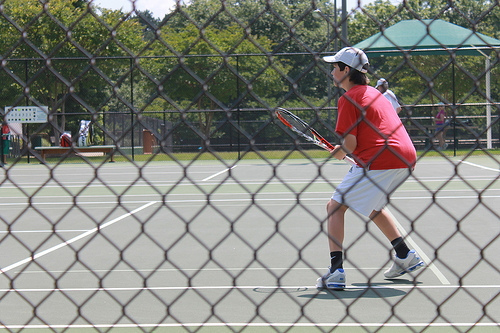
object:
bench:
[35, 145, 117, 164]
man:
[314, 46, 423, 290]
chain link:
[206, 175, 253, 223]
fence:
[0, 0, 500, 333]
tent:
[348, 16, 498, 148]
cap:
[322, 46, 371, 74]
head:
[330, 47, 370, 88]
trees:
[133, 1, 294, 129]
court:
[0, 147, 500, 333]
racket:
[274, 107, 359, 169]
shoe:
[315, 266, 346, 290]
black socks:
[390, 236, 410, 259]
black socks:
[330, 250, 343, 273]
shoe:
[383, 250, 425, 279]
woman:
[433, 102, 449, 151]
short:
[330, 162, 412, 217]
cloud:
[90, 1, 191, 22]